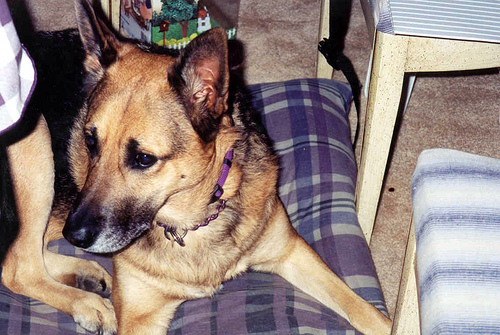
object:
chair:
[386, 147, 500, 335]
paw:
[73, 293, 118, 333]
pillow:
[409, 135, 499, 334]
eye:
[131, 149, 156, 169]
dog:
[0, 0, 396, 334]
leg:
[351, 28, 404, 248]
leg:
[260, 227, 396, 334]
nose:
[59, 220, 96, 247]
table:
[353, 0, 500, 249]